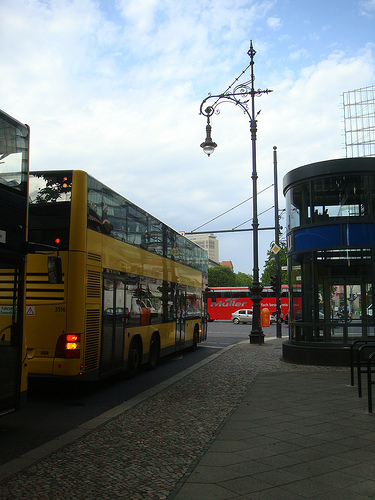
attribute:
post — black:
[272, 144, 283, 338]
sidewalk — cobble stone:
[2, 332, 373, 499]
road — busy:
[0, 318, 291, 466]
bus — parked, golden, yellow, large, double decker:
[29, 170, 207, 384]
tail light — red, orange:
[66, 332, 80, 352]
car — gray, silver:
[230, 306, 254, 326]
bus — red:
[205, 283, 299, 323]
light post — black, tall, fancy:
[198, 37, 274, 345]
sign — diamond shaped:
[271, 242, 281, 256]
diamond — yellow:
[272, 245, 279, 253]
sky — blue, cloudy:
[0, 0, 375, 281]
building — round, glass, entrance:
[282, 155, 375, 362]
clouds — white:
[3, 1, 375, 270]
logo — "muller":
[210, 298, 251, 310]